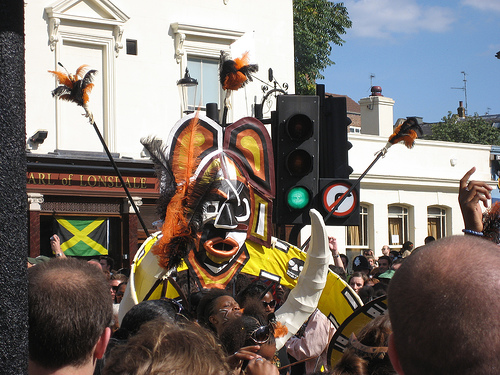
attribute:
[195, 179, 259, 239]
mask — white, black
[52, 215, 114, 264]
flag — green, black, yellow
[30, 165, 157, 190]
letter — golden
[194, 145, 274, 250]
mask — brown, white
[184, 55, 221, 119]
window — frontal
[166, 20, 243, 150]
frame — white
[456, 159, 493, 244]
hand — lifted up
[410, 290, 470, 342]
hair — short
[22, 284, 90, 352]
hair — short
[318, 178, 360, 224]
sign — road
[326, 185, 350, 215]
symbol — international no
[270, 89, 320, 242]
light — traffic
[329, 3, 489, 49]
clouds — white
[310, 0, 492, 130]
sky — blue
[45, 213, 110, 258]
flag — black, yellow, green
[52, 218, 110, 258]
flag — Jamaican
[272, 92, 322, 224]
street light — black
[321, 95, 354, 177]
street light — black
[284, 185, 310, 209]
light — green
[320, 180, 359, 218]
sign — round, indicating no right turn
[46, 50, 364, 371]
costume — large, bright colored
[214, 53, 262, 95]
feathers — black, orange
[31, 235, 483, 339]
crowd — large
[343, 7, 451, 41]
clouds — small, wispy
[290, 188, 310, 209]
light — green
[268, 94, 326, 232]
traffic signal — black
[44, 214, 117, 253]
flag — black, green, yellow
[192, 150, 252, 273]
mask — colorful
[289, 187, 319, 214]
light — green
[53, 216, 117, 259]
flag — green, yellow, black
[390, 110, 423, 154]
feathers — orange, blck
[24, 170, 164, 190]
writing — gold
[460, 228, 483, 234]
bracelet — bead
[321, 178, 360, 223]
street sign — round, red, white, black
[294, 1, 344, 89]
tree — tall, green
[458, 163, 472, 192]
finger — upraised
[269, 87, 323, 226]
light — traffic, green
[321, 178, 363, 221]
sign — no right turn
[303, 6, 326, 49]
leaves — green, yellow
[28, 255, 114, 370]
head — man's, balding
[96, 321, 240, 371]
hair — light brown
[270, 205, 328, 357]
horn — fake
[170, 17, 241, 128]
window — white, fancy edged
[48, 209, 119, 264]
flag — green, yellow, black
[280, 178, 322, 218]
light — green, illuminated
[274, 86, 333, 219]
signal — traffic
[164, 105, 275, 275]
mask — colorful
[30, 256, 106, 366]
hair — dark, short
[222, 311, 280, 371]
head — person's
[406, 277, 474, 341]
hair — short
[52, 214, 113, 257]
flag — yellow, green, black